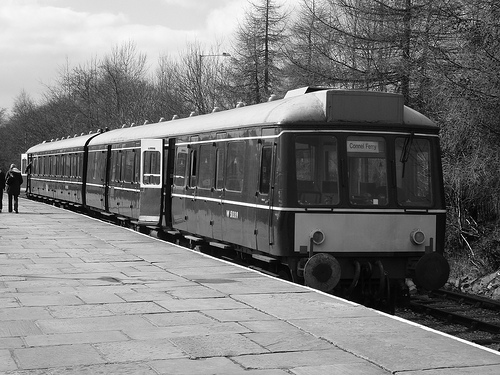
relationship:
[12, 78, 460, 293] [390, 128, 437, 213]
train has windows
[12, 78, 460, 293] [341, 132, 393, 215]
train has windows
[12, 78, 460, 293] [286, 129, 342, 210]
train has windows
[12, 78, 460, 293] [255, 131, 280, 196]
train has windows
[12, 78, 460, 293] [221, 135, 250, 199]
train has windows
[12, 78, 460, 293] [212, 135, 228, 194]
train has windows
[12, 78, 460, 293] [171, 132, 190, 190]
train has windows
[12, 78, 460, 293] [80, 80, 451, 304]
train has cars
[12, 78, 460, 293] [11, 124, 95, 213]
train has cars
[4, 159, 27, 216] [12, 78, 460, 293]
person waiting train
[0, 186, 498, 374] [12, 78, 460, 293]
sidewalk beside train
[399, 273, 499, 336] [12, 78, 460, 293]
track front train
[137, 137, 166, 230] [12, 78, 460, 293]
door on train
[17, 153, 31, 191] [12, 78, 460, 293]
door of train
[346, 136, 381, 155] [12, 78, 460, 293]
sign on train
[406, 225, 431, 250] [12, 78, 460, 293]
headlight on train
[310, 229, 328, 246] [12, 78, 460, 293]
headlight on train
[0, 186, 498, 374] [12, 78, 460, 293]
sidewalk by train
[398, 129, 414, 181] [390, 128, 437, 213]
wiper on windows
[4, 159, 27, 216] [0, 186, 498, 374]
person on sidewalk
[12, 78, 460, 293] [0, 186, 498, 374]
train at sidewalk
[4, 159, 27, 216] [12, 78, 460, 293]
person near train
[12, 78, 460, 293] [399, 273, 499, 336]
train on track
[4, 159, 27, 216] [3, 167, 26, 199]
person wearing coat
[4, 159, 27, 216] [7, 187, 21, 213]
person wearing pants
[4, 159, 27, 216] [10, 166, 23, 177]
person wearing hat